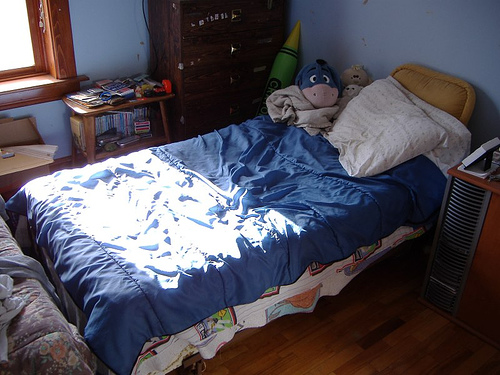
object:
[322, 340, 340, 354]
wooden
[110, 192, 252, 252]
light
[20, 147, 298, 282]
sun shine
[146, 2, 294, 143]
dresser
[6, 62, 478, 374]
bed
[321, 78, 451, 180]
pillow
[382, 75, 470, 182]
pillow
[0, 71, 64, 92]
window sill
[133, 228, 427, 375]
sheet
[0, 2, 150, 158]
wall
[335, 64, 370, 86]
teddy bear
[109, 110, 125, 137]
books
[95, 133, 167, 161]
bookshelf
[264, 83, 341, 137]
towel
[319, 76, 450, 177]
pillowcase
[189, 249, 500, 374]
flooring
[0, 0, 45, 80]
window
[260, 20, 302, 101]
crayon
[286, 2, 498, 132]
wall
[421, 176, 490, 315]
vent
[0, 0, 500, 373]
room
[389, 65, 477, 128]
headboard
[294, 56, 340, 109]
eeyore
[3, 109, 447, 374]
comforter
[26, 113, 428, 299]
mattress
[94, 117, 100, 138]
books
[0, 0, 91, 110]
window frame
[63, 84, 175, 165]
table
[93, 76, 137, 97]
magazines